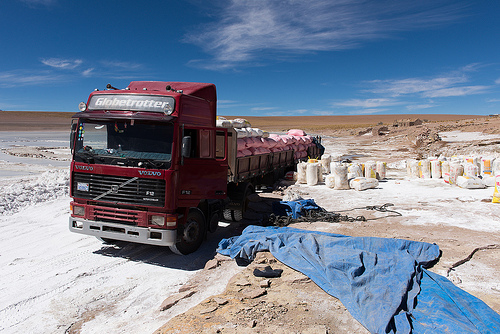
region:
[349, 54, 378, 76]
part of the sky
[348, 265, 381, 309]
part of a tent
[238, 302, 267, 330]
part of a ground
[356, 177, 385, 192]
part of some sacks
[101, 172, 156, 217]
front of a track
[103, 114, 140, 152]
part of a window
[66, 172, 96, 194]
part of a truck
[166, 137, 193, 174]
part of a side mirror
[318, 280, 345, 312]
edge of a tent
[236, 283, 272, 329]
part of a rock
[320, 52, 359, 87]
part of the sky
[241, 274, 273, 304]
part of the ground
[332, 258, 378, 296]
part of a tent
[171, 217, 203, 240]
part of a rim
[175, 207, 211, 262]
part of a wheel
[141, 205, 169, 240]
part of a headlight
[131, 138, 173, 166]
part of a window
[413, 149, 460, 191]
part of some sacks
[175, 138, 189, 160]
part of a side mirror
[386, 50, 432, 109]
part of a cloud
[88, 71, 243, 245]
The truck is red.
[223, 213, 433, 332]
The sheet on the ground is blue.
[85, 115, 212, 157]
No one is in the truck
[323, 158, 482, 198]
Bags of sand on the ground.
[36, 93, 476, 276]
A truck in the desert.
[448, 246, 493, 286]
A black cord on the ground.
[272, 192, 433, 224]
Rope is on the ground.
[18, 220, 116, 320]
The sand is white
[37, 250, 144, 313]
Tire wheels are in the sand.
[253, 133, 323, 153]
Pink bags on the truck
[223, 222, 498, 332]
large blue plastic tarp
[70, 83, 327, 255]
a red Volvo semi truck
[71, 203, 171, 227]
headlights of a red Volvo semi truck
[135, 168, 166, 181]
a silver colored Volvo logo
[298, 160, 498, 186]
many bags of sand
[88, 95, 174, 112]
Globetrotter logo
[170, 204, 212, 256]
front left tire of a Volvo semi truck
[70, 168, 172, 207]
grill of a semi truck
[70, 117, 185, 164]
windshield of a red Volvo semi truck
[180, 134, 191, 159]
a semi truck's driver side mirror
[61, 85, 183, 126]
White letters that spell globetrotter.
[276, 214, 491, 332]
Blue tarp on ground.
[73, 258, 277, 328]
Rocky and sandy soil.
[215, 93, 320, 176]
Red and white sand bags on truck.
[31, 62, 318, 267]
Red semi that says volvo on it.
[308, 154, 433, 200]
Bags of concrete.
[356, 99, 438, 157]
Brown house off in distance.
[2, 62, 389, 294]
Semi truck on the sand.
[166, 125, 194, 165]
Side mirror on truck.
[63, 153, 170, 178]
Two silver volvo symbols.